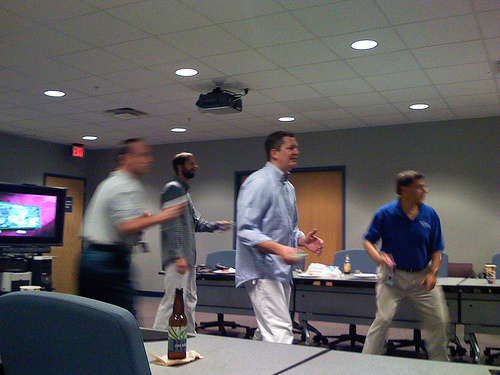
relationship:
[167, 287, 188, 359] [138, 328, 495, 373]
bottle on table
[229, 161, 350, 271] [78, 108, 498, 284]
door against wall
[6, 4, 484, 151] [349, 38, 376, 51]
ceiling recessed light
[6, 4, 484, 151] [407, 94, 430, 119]
ceiling recessed lighting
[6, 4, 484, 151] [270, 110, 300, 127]
ceiling recessed lighting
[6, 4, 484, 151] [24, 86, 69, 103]
ceiling recessed lighting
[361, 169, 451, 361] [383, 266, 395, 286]
guy holding remote control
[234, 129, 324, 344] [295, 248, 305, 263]
guy holding remote control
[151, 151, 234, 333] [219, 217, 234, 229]
man holding remote control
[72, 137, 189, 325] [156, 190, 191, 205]
man holding remote control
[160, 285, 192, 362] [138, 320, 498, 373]
bottle on table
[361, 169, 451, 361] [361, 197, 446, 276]
guy wearing blue polo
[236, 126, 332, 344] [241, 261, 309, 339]
guy wearing pants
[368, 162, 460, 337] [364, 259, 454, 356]
guy wearing pants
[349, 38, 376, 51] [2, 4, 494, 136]
light on ceiling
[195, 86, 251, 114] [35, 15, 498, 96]
projection on ceiling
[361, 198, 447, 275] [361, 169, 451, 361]
shirt on guy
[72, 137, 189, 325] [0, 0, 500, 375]
man in conference room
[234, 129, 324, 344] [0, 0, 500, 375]
guy in conference room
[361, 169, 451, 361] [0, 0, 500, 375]
guy in conference room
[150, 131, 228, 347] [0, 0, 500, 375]
man in conference room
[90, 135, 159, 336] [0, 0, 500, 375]
man in conference room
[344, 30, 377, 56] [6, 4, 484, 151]
light in ceiling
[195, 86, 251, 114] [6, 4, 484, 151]
projection on ceiling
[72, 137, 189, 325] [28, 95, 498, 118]
man in conference room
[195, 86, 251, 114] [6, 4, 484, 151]
projection hanging from ceiling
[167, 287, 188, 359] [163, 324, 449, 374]
bottle of beer on table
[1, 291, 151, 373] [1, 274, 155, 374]
chair on left corner